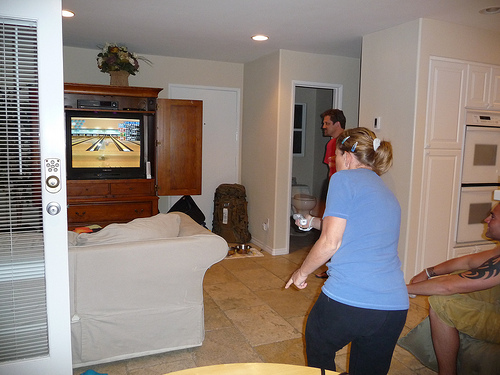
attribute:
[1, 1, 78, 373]
door — glass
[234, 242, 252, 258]
bowl — silver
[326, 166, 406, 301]
shirt — light, blue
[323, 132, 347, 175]
shirt — red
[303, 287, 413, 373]
pants — blue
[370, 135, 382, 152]
scrunchie — white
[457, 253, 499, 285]
tattoo — green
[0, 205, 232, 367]
couch — white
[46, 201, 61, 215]
door knob — silver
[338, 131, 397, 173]
hair — blonde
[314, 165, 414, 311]
shirt — blue, red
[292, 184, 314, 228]
toilet — white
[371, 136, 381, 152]
hair tie — white, small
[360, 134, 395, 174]
pony tail — blonde, long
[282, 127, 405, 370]
woman — nice, middle aged, pretty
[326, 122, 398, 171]
hair — blonde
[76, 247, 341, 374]
tile — ceramic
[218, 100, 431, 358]
woman — nice, pretty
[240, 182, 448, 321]
shirt — blue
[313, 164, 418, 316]
top — blue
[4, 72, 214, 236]
cabinet — wood, brown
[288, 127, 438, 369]
woman — pretty